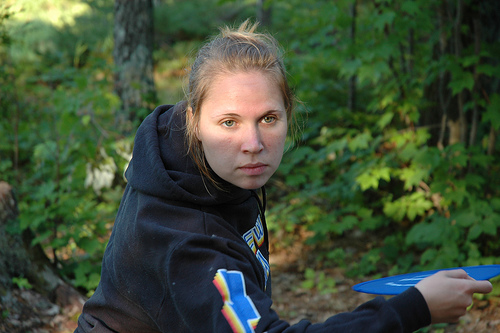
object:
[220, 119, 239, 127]
eye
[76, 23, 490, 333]
woman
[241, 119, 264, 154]
nose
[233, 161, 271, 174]
mouth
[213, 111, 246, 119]
brow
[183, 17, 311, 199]
hair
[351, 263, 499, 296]
frisbee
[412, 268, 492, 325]
hand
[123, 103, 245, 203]
hood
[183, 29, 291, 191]
head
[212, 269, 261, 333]
logo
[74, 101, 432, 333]
shirt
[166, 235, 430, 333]
sleeve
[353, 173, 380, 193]
leaf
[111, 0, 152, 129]
trunk